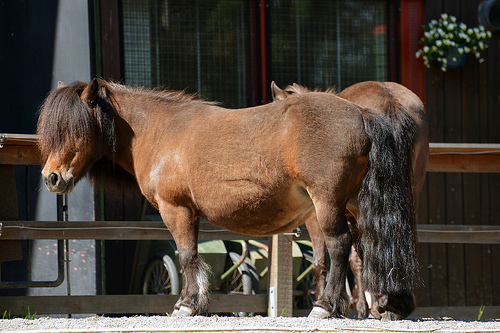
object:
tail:
[356, 112, 429, 294]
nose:
[40, 170, 61, 193]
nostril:
[47, 172, 60, 187]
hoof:
[175, 291, 200, 317]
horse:
[31, 78, 421, 322]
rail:
[0, 133, 499, 322]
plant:
[412, 10, 491, 73]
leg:
[300, 185, 370, 304]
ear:
[78, 76, 101, 104]